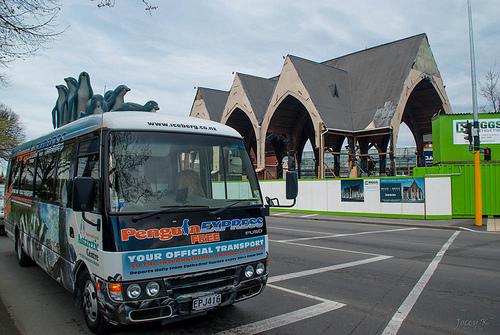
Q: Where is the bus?
A: On the street.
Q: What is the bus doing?
A: It's parked.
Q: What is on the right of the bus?
A: A pavilion.